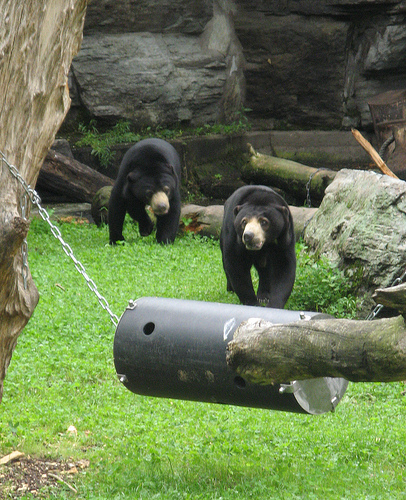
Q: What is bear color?
A: Black.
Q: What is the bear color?
A: Black.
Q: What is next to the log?
A: A black bear.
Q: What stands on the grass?
A: A black bear.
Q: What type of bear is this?
A: A black bear.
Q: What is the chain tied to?
A: A tree.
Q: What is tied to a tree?
A: A chain.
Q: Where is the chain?
A: Tied to a tree.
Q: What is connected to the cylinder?
A: A chain which is tied to a tree.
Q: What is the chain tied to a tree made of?
A: The chain in metal.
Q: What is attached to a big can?
A: Chains.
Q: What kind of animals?
A: Bears.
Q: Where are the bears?
A: On the grass.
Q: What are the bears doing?
A: Walking.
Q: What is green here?
A: The grass.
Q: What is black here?
A: The bears.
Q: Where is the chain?
A: On the tree.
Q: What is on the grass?
A: Bears.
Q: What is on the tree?
A: A chain.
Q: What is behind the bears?
A: Boulders.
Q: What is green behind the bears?
A: Plants.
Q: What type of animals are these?
A: Bears.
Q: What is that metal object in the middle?
A: A bear toy.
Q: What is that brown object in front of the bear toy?
A: A log.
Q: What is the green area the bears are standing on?
A: Grass.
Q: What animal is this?
A: Bears.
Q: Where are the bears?
A: Zoo.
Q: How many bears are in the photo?
A: Two.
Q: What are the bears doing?
A: Walking.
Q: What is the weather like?
A: Sunny.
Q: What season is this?
A: Summer.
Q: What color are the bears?
A: Black.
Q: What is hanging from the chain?
A: Barrel.